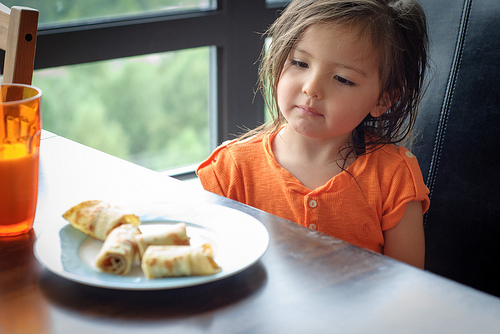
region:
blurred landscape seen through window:
[31, 45, 221, 175]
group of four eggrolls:
[61, 196, 223, 278]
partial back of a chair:
[1, 1, 39, 84]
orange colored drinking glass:
[1, 81, 42, 248]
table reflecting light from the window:
[1, 127, 498, 332]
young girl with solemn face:
[194, 0, 431, 270]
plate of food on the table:
[33, 196, 270, 291]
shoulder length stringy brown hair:
[226, 2, 427, 217]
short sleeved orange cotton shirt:
[192, 123, 432, 255]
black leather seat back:
[403, 1, 499, 297]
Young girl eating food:
[191, 0, 439, 280]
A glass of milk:
[0, 72, 44, 243]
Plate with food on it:
[29, 195, 276, 302]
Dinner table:
[0, 95, 499, 332]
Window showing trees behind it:
[0, 0, 417, 263]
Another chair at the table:
[1, 2, 46, 127]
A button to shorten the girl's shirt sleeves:
[396, 140, 430, 201]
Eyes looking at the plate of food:
[280, 51, 365, 96]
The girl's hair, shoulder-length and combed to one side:
[229, 0, 433, 171]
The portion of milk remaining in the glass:
[0, 142, 40, 237]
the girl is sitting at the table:
[8, 8, 476, 295]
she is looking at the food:
[49, 15, 435, 290]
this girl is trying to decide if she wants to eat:
[85, 45, 376, 289]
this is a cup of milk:
[0, 71, 43, 253]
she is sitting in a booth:
[200, 11, 494, 294]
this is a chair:
[2, 1, 53, 111]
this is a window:
[24, 61, 253, 183]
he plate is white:
[173, 206, 268, 285]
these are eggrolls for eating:
[105, 226, 217, 271]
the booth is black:
[408, 3, 495, 280]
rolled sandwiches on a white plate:
[39, 188, 267, 300]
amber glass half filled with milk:
[0, 80, 45, 240]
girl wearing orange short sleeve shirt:
[185, 0, 430, 260]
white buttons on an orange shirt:
[292, 190, 327, 235]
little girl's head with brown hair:
[231, 0, 436, 167]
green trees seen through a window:
[17, 30, 234, 181]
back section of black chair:
[340, 0, 489, 278]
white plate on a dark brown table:
[29, 181, 274, 302]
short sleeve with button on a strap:
[359, 140, 430, 230]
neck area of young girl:
[258, 119, 373, 181]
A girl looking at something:
[244, 0, 440, 146]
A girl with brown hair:
[209, 0, 446, 233]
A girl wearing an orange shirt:
[204, 0, 446, 216]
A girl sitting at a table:
[184, 0, 489, 265]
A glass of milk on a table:
[0, 72, 50, 262]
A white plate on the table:
[39, 168, 309, 328]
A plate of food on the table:
[33, 171, 279, 317]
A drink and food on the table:
[1, 77, 273, 299]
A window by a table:
[34, 15, 231, 178]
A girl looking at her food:
[38, 0, 431, 293]